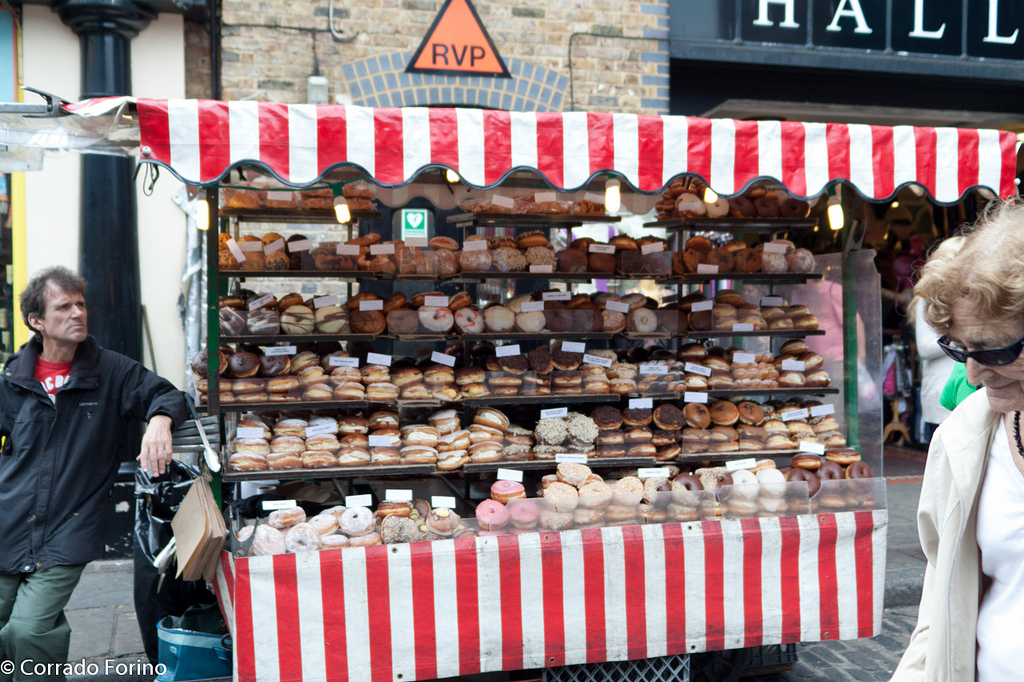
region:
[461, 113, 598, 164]
The red and white cover of a cart roof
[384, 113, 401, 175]
A red stripe on the side of the roof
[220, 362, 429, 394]
Stacks of donuts on a cart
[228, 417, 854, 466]
a shelf with several doughnuts on it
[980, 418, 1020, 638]
a woman wearing a white shirt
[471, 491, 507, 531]
A piece of food.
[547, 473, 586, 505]
A piece of food.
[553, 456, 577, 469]
A piece of food.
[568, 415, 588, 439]
A piece of food.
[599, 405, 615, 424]
A piece of food.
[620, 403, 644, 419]
A piece of food.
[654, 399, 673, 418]
A piece of food.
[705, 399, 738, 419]
A piece of food.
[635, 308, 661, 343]
A piece of food.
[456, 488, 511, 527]
donut stacked on the cart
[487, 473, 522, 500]
donut stacked on the cart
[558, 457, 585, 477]
donut stacked on the cart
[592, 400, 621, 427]
donut stacked on the cart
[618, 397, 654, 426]
donut stacked on the cart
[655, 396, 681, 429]
donut stacked on the cart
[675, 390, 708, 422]
donut stacked on the cart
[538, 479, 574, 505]
donut stacked on the cart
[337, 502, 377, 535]
donut stacked on the cart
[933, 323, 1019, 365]
dark black sunglasses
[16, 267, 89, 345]
person has a head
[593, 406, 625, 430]
donut is brown and black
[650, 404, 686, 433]
donut is brown and black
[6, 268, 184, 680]
man standing wearing black jacket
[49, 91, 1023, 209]
red and white striped awning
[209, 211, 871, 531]
a bunch of donuts on donut cart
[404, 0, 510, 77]
black and orange triangle sign in the wall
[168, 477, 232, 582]
bags hanging on donut cart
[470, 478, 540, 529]
a bunch of pink donuts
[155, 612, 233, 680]
dark and light blue bag in the floor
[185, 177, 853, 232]
lights hanging from red and white awning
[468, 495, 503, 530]
A donut on a stand.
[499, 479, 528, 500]
A donut on a stand.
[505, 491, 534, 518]
A donut on a stand.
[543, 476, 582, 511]
A donut on a stand.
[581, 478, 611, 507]
A donut on a stand.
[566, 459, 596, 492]
A donut on a stand.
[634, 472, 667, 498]
A donut on a stand.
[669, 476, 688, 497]
A donut on a stand.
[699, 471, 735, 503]
A donut on a stand.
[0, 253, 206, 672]
man with a black jacket